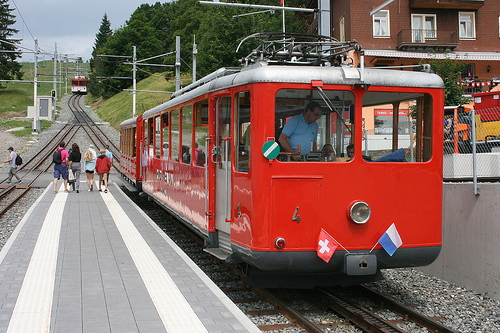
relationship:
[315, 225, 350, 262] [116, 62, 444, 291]
flag in front of train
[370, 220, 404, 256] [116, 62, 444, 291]
flag in front of train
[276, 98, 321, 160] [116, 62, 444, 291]
man on train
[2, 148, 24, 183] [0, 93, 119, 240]
man crossing train tracks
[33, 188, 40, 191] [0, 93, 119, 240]
rock under train tracks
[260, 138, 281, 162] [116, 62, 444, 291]
sign in front of train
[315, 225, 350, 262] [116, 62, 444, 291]
flag on train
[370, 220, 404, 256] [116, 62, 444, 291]
flag on train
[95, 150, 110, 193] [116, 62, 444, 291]
person near train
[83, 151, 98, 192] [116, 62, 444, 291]
person near train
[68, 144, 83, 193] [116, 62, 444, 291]
person near train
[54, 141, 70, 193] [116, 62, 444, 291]
person near train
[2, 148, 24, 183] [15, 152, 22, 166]
man with backpack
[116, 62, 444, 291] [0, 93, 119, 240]
train on train tracks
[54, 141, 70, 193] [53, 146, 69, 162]
person wearing shirt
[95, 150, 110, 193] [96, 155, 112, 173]
person wearing jacket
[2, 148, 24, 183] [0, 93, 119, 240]
man walking over train tracks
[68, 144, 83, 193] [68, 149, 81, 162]
person wearing shirt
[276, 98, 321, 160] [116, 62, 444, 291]
man inside train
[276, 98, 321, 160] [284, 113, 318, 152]
man has shirt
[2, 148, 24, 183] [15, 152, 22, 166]
man has backpack